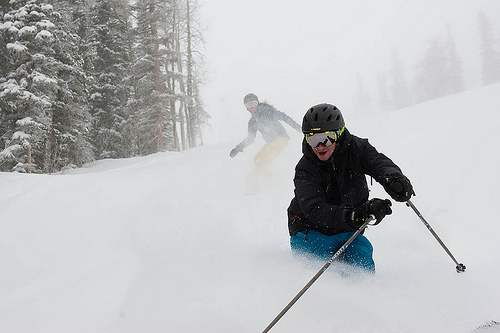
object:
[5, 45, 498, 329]
ski slope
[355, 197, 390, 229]
glove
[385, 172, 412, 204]
glove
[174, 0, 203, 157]
tree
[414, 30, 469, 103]
tree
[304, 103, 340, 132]
helmet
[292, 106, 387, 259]
person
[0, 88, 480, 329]
field